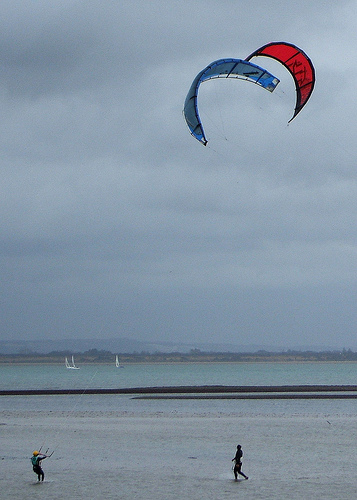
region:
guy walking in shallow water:
[217, 422, 268, 499]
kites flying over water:
[6, 37, 332, 491]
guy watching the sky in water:
[215, 437, 299, 499]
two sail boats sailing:
[64, 335, 152, 385]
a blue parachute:
[165, 27, 323, 167]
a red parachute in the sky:
[238, 5, 316, 168]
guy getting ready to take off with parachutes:
[16, 34, 339, 476]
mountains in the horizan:
[17, 317, 351, 381]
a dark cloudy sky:
[18, 237, 345, 405]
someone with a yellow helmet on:
[27, 440, 64, 485]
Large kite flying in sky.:
[251, 37, 318, 99]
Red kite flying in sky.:
[250, 38, 322, 85]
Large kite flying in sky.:
[188, 44, 244, 121]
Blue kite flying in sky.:
[167, 63, 256, 144]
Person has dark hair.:
[237, 440, 248, 454]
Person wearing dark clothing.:
[219, 447, 254, 495]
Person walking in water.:
[206, 467, 261, 494]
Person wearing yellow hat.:
[29, 446, 55, 458]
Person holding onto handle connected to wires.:
[40, 442, 69, 495]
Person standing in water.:
[24, 472, 58, 482]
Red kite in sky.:
[277, 48, 323, 90]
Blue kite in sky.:
[167, 81, 237, 126]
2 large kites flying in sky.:
[167, 28, 331, 166]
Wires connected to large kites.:
[217, 142, 338, 211]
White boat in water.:
[106, 358, 132, 369]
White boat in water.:
[62, 357, 88, 376]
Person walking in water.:
[215, 471, 262, 484]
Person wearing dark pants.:
[216, 463, 252, 482]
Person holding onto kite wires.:
[22, 467, 56, 483]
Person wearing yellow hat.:
[29, 450, 43, 458]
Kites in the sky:
[181, 42, 315, 146]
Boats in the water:
[62, 354, 121, 367]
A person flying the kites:
[31, 449, 46, 481]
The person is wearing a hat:
[31, 449, 40, 456]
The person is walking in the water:
[231, 445, 249, 481]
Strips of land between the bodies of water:
[0, 384, 356, 401]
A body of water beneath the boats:
[1, 362, 356, 385]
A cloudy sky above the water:
[0, 1, 354, 343]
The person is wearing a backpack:
[30, 454, 40, 464]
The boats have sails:
[62, 354, 123, 369]